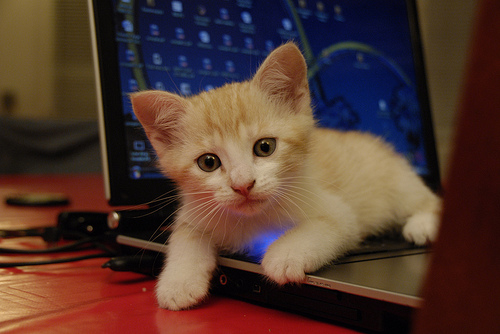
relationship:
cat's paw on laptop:
[257, 243, 324, 280] [92, 1, 445, 305]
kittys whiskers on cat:
[174, 187, 320, 223] [123, 37, 446, 310]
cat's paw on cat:
[257, 243, 324, 280] [123, 37, 446, 310]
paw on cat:
[155, 261, 210, 307] [123, 37, 446, 310]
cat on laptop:
[114, 41, 455, 267] [92, 1, 445, 305]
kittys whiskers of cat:
[187, 188, 211, 197] [123, 37, 446, 310]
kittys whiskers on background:
[187, 188, 211, 197] [4, 2, 499, 309]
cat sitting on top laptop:
[123, 37, 446, 310] [324, 30, 449, 148]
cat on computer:
[123, 37, 446, 310] [89, 1, 467, 305]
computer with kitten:
[75, 0, 435, 320] [128, 72, 448, 312]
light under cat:
[245, 230, 285, 260] [123, 37, 446, 310]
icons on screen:
[124, 5, 302, 115] [110, 0, 441, 177]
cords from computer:
[12, 202, 122, 271] [84, 7, 445, 314]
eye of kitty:
[248, 138, 278, 159] [134, 94, 445, 325]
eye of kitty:
[188, 151, 224, 172] [134, 94, 445, 325]